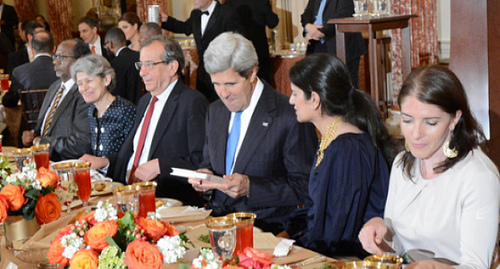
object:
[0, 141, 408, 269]
dinner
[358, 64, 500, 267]
woman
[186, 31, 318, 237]
man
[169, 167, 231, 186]
book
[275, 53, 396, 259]
woman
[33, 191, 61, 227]
roses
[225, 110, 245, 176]
tie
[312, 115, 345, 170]
necklace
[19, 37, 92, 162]
people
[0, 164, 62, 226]
bouquet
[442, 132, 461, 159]
earring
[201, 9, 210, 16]
tie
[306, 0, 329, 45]
shirt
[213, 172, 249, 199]
hands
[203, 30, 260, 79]
hair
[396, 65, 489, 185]
hair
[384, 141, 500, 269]
shirt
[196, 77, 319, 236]
jacket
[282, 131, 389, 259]
dress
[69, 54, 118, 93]
hair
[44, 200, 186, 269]
flower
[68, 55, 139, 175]
woman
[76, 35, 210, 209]
man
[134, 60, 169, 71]
glasses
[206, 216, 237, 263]
drinks